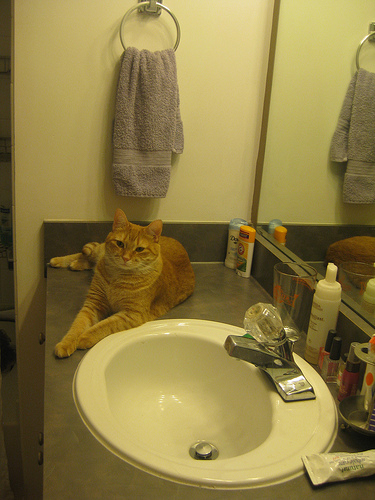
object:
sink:
[72, 318, 340, 491]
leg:
[50, 253, 87, 270]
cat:
[50, 208, 195, 359]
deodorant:
[228, 218, 247, 229]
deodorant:
[236, 225, 257, 278]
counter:
[42, 264, 375, 500]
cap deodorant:
[239, 226, 256, 243]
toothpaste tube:
[301, 450, 374, 487]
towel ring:
[118, 1, 180, 53]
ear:
[145, 219, 163, 238]